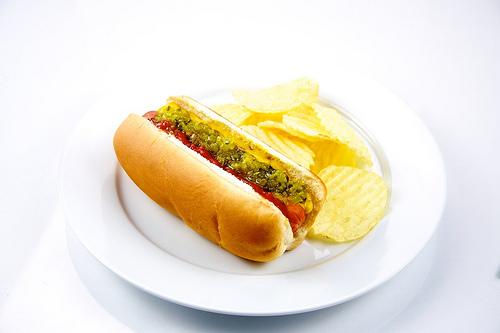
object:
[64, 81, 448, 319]
plate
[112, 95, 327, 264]
hotdog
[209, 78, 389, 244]
chips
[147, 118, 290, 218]
ketchup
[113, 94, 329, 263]
bun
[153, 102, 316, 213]
mustard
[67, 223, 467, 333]
shadow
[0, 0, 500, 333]
table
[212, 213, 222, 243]
line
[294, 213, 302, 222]
line